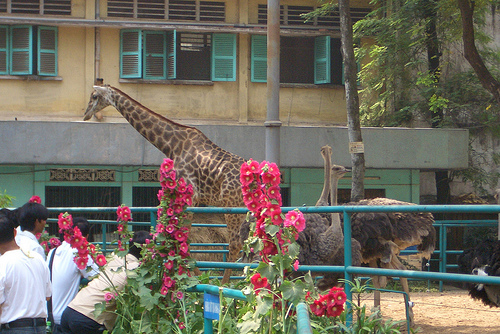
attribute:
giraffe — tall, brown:
[91, 92, 295, 257]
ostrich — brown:
[331, 146, 432, 318]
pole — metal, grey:
[248, 5, 290, 166]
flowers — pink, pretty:
[60, 156, 346, 312]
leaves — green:
[349, 2, 498, 127]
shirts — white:
[10, 215, 93, 318]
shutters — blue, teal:
[4, 27, 332, 82]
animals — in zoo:
[94, 57, 498, 297]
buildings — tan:
[7, 4, 499, 272]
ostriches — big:
[271, 138, 428, 320]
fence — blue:
[219, 205, 489, 319]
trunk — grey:
[346, 2, 358, 195]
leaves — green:
[93, 254, 383, 333]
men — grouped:
[6, 190, 113, 334]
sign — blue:
[202, 295, 233, 322]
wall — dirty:
[10, 81, 353, 123]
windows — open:
[159, 26, 218, 80]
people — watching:
[19, 195, 163, 333]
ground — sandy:
[356, 283, 499, 329]